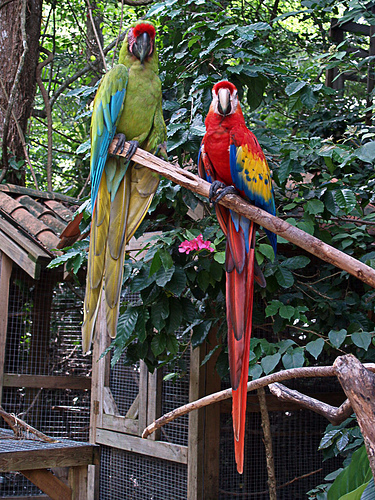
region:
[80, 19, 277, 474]
Two colorful parrots on a stick.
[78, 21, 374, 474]
Parrots sitting on a stick.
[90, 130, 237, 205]
Claws on two parrots.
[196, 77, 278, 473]
Red, blue, yellow, and white parrot.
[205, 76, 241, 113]
White and red faced parrot.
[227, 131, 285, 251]
Blue, yellow, and red parrot's wing.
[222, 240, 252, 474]
Blue and red tail feather.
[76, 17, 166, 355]
Green, blue, red, and yellow parrot bird.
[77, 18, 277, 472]
Parrot birds in the woods.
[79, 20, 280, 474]
Parrot birds sitting on branch.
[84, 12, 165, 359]
Long green Macaw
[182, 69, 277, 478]
Long red Macaw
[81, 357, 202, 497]
Door on bird cage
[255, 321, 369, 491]
Leaves and branches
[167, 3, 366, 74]
Leaves on a tree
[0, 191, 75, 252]
Roof tiles on top of bird cage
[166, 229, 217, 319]
Flowers and leaves on wild trees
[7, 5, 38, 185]
Tree trunk behind bird cages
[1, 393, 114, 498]
Edge of wooden table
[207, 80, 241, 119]
Face of Macaw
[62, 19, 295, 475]
two Macaws perched on a branch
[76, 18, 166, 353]
the parrot is a military macaw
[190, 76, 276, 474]
the parrot is a scarlet macaw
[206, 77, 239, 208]
the macaw has a white beak and long black claws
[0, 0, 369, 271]
green trees are behind the macaws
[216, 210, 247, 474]
the bird has long tail feathers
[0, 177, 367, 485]
the bird cages are wooden and wire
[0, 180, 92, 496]
a barrel tile roof is on the cage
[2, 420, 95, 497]
a perch is outside a cage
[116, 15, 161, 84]
the macaw has a black beak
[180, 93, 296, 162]
Parrot on a branch.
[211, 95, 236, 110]
The parrot's beak is white.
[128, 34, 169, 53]
The parrot's beak is black.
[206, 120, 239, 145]
The parrot has red feathers.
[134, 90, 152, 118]
The parrot has green feathers.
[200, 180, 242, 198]
The parrot has black feet.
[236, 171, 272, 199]
The parrot has blue and yellow wings.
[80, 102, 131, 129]
The parrot has green and blue feathers.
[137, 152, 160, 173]
The branch is tan.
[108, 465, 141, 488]
There is a door on the cage.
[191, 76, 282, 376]
multi colored bird on a perch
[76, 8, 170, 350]
multi colored bird on a perch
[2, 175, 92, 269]
roof of bird cage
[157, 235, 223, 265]
tree with pink flowers and green leaves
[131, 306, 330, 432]
limb in a bird enclosure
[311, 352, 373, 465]
limb in a bird enclosure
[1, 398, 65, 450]
limb in a bird enclosure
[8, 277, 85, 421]
bird cage in a bird enclosure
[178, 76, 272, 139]
bill of multi colored bird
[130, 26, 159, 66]
black bill of multi colored bird